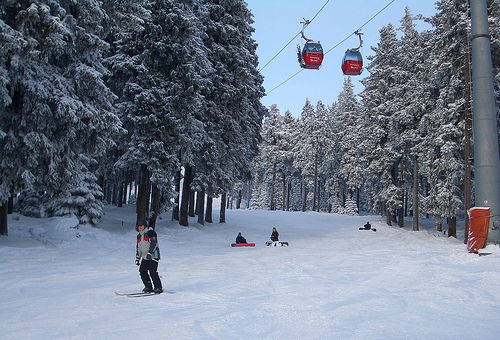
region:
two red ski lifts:
[298, 16, 363, 76]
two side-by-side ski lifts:
[295, 16, 366, 73]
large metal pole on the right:
[466, 0, 497, 237]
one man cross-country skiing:
[119, 215, 171, 299]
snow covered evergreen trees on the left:
[3, 0, 264, 240]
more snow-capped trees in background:
[223, 2, 495, 237]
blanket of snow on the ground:
[1, 207, 499, 337]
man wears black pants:
[118, 215, 173, 302]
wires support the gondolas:
[253, 0, 391, 100]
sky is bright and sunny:
[255, 2, 454, 120]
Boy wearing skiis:
[128, 216, 175, 305]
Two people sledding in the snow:
[227, 218, 284, 249]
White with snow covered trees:
[30, 13, 123, 203]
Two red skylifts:
[295, 28, 363, 73]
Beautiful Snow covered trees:
[275, 105, 457, 213]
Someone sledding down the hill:
[360, 217, 376, 232]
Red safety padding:
[465, 202, 490, 257]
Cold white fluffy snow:
[215, 255, 438, 338]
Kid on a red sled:
[230, 226, 256, 248]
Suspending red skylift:
[288, 14, 325, 69]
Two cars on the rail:
[296, 17, 365, 79]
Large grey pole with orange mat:
[465, 0, 499, 252]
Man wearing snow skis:
[115, 215, 169, 299]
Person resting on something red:
[229, 227, 258, 250]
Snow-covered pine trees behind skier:
[1, 0, 270, 237]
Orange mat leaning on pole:
[464, 204, 494, 256]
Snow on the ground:
[1, 208, 498, 337]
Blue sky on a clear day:
[246, 0, 442, 122]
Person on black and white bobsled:
[265, 223, 291, 249]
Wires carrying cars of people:
[252, 2, 397, 93]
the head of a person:
[131, 214, 153, 234]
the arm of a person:
[146, 227, 158, 253]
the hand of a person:
[143, 248, 155, 262]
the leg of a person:
[147, 256, 162, 287]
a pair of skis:
[109, 280, 178, 304]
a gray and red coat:
[131, 224, 163, 264]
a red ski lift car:
[291, 38, 330, 72]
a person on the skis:
[127, 214, 167, 299]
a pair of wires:
[255, 0, 395, 100]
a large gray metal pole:
[461, 0, 498, 244]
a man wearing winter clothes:
[114, 218, 176, 298]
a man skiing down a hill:
[116, 218, 168, 298]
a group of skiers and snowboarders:
[117, 215, 379, 297]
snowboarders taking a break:
[231, 221, 376, 249]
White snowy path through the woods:
[0, 206, 499, 339]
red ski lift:
[255, 1, 498, 249]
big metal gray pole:
[469, 0, 498, 250]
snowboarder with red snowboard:
[231, 231, 255, 249]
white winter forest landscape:
[1, 0, 498, 237]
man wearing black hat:
[116, 221, 169, 296]